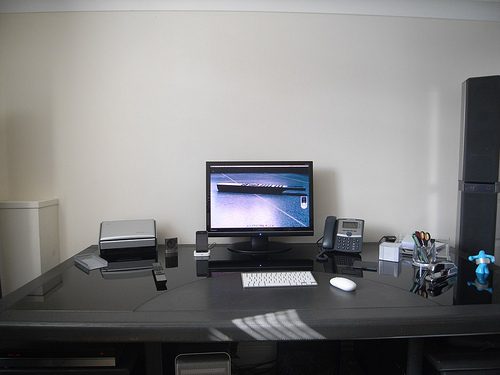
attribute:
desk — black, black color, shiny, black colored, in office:
[3, 240, 499, 341]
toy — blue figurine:
[468, 247, 495, 276]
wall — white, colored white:
[0, 14, 500, 261]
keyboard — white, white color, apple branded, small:
[238, 271, 317, 288]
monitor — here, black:
[205, 159, 314, 253]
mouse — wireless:
[330, 275, 357, 292]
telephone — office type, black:
[315, 215, 365, 261]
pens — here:
[409, 231, 428, 262]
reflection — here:
[209, 308, 325, 341]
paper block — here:
[378, 242, 402, 262]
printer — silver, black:
[97, 218, 157, 258]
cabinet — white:
[1, 199, 58, 295]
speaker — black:
[165, 237, 179, 256]